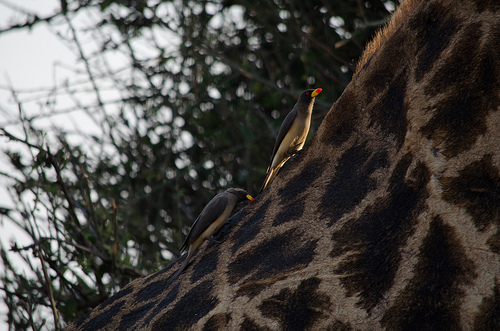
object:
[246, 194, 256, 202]
beak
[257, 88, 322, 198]
bird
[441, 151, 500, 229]
spot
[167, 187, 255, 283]
bird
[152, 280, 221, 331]
spot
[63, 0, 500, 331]
giraffe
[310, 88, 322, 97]
beak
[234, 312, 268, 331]
spot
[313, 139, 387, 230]
spot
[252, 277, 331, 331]
brown spot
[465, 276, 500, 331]
spot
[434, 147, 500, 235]
spot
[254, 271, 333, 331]
spot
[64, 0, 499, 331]
back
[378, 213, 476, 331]
spot